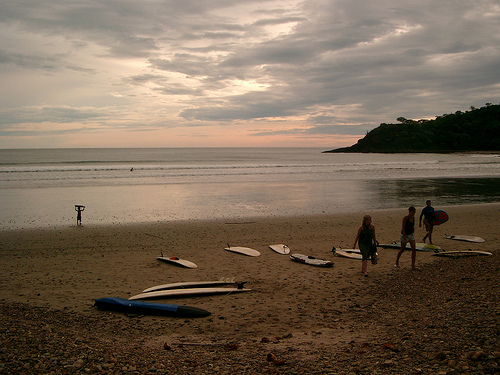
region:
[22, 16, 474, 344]
photograph of beach at sun set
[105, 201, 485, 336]
many surfboards on the beach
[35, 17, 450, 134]
sky covered with grey and white clouds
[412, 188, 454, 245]
person walking with a surfboard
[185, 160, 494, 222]
sand wet from crashing waves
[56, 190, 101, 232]
small child standing on the beach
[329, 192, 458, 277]
three people walking on beach away from ocean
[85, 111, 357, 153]
sky pink from sun set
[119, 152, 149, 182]
one person in the ocean surfing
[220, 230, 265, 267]
white surfboard on the beach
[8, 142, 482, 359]
sand and water near shore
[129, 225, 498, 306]
surf boards in the sand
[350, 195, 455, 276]
people walking away from water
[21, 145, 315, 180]
water section of the beach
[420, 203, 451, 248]
person with surf board in hand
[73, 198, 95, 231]
person carrying surf board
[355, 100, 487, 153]
elevated area with trees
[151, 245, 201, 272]
a board in the sand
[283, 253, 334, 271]
board with decorative design on it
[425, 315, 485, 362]
rocks and gravel in sand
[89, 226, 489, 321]
The surf boards are on the beach.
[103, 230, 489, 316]
The surf boards are on the sand.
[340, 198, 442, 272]
The people are walking.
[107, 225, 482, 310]
The surf boards are white.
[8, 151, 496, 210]
The water is calm.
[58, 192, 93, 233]
They are standing in the water.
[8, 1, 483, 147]
The sky is cloudy.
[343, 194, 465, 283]
They are on the sand.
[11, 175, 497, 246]
The water is on the shore.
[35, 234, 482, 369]
The sand is brown.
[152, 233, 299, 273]
three surfboards on the beach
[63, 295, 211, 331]
blue surfboard lying on ground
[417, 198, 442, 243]
person with board in his hand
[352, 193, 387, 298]
female walking up the beach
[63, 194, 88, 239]
person with board over head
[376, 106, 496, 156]
hills in the background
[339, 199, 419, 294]
man and woman walking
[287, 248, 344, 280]
black and white surfboard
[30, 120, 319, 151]
sky is a light red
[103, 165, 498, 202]
water is dark and calm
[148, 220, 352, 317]
Surfboards on the beach.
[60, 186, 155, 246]
Person by the water.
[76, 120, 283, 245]
Water by the beach.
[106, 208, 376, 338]
Sand on the beach.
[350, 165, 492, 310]
People on the beach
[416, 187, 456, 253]
Person carrying a surfboard.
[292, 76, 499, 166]
Trees on the hill.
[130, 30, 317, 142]
Clouds in the sky.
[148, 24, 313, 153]
White clouds in the sky.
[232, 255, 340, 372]
Footsteps in the sand.